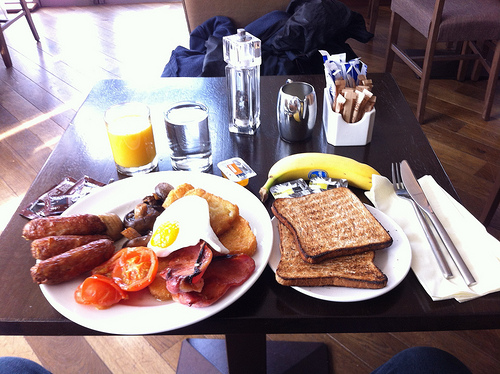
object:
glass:
[105, 102, 159, 176]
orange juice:
[109, 119, 156, 167]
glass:
[164, 102, 213, 172]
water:
[164, 105, 212, 161]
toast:
[271, 187, 393, 262]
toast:
[276, 221, 389, 289]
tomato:
[74, 274, 125, 309]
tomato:
[111, 246, 157, 292]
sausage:
[21, 214, 107, 241]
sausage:
[29, 234, 109, 260]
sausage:
[30, 238, 115, 285]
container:
[322, 86, 376, 147]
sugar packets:
[333, 75, 377, 123]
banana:
[258, 152, 381, 203]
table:
[0, 77, 500, 373]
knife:
[400, 159, 478, 289]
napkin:
[364, 173, 500, 304]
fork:
[391, 162, 454, 280]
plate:
[268, 202, 413, 303]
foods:
[22, 182, 259, 311]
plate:
[35, 170, 274, 338]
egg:
[146, 195, 230, 257]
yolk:
[150, 221, 178, 249]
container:
[217, 156, 258, 187]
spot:
[268, 174, 273, 179]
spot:
[368, 180, 372, 184]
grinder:
[223, 28, 262, 134]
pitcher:
[276, 78, 317, 145]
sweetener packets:
[318, 49, 368, 83]